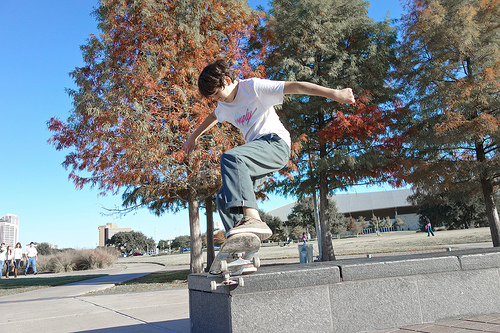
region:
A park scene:
[18, 17, 497, 321]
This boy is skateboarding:
[170, 51, 366, 298]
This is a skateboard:
[192, 227, 273, 303]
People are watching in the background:
[0, 240, 45, 282]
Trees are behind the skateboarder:
[51, 3, 496, 283]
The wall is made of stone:
[168, 247, 498, 329]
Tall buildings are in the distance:
[0, 205, 141, 247]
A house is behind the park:
[272, 184, 477, 232]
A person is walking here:
[414, 211, 449, 242]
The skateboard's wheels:
[207, 254, 262, 293]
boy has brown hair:
[194, 56, 236, 98]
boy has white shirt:
[207, 60, 291, 150]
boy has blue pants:
[219, 131, 290, 231]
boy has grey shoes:
[227, 199, 290, 257]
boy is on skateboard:
[194, 242, 247, 289]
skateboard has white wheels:
[206, 246, 241, 278]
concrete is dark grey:
[201, 225, 480, 324]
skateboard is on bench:
[205, 206, 437, 325]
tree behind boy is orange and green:
[52, 3, 263, 256]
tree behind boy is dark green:
[246, 11, 393, 253]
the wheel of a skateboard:
[217, 260, 226, 272]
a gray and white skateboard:
[195, 233, 262, 290]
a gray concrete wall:
[185, 243, 499, 331]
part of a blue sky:
[3, 1, 94, 245]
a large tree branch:
[461, 50, 498, 247]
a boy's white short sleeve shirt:
[215, 77, 294, 147]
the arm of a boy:
[252, 80, 336, 103]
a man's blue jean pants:
[25, 254, 36, 273]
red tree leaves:
[317, 90, 387, 142]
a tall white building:
[0, 212, 23, 251]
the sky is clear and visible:
[6, 41, 72, 144]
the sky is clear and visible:
[17, 27, 101, 161]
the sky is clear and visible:
[9, 58, 151, 252]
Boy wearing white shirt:
[245, 80, 266, 100]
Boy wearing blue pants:
[226, 155, 251, 190]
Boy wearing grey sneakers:
[221, 220, 276, 235]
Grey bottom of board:
[225, 232, 261, 252]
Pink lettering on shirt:
[225, 105, 260, 125]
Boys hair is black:
[193, 56, 218, 89]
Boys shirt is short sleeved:
[249, 72, 293, 110]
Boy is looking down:
[188, 54, 250, 114]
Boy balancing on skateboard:
[154, 43, 362, 297]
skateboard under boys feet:
[192, 231, 282, 296]